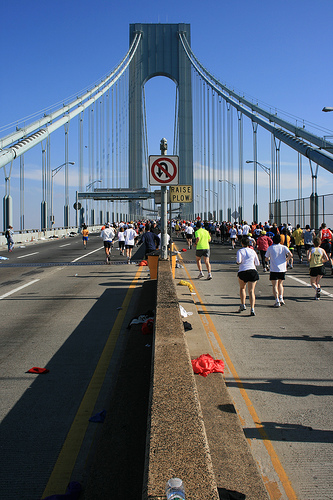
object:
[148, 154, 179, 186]
sign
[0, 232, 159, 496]
route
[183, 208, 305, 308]
group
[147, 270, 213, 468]
barrier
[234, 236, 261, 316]
women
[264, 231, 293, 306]
man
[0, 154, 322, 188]
cloud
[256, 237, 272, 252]
jacket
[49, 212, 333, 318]
race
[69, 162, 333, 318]
marathon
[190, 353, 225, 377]
plastic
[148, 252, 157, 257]
lid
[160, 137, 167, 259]
lightpost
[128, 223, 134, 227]
hats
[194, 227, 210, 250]
shirt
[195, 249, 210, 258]
shorts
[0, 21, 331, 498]
bridge